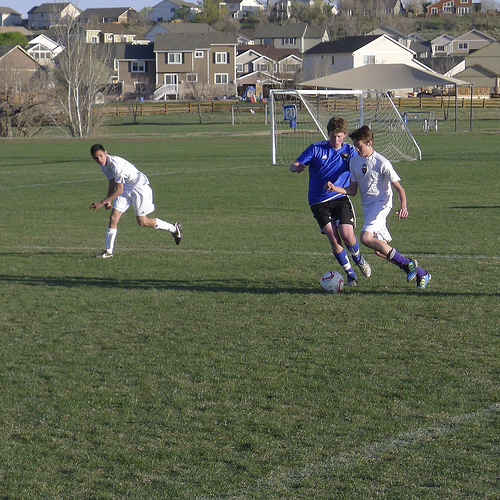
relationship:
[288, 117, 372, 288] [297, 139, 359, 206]
boy wearing uniform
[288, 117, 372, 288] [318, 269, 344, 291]
boy kicking ball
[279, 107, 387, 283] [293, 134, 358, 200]
boy wearing t-shirt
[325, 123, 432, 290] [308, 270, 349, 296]
player run for ball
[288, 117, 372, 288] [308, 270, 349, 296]
boy run for ball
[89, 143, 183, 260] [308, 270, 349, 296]
children run for ball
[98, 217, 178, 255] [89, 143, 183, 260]
white socks on children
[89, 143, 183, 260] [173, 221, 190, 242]
children wearing cleats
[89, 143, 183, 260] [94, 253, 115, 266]
children wearing cleats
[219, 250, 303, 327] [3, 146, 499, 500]
shadows on field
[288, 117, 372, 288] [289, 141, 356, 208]
boy wearing a blue jersey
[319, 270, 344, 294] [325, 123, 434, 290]
ball chased by player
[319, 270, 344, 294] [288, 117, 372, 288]
ball chased by boy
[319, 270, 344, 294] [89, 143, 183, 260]
ball chased by children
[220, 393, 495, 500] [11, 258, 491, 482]
line on field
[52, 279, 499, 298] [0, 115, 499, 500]
shadows on field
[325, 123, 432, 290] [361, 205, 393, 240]
player wearing shorts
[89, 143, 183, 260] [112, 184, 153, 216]
children wearing shorts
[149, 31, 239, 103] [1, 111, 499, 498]
house behind soccer field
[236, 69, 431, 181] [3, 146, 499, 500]
goal on field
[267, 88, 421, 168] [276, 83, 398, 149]
goal a mesh cage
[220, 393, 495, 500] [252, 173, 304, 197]
line on field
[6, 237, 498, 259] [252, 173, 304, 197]
line on field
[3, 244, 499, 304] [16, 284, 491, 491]
shadows on grass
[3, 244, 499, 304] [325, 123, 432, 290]
shadows of player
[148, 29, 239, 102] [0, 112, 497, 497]
home skirts field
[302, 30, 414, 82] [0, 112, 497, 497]
home skirts field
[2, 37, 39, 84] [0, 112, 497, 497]
home skirts field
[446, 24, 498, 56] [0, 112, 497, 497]
home skirts field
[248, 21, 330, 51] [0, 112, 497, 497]
home skirts field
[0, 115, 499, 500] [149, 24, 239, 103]
field behind house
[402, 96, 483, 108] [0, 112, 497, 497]
fence around field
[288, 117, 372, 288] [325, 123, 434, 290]
boy opposes player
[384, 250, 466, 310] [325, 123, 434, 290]
shoes on player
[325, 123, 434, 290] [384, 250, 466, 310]
player wears shoes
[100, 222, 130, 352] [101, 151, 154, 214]
left shoe of player on left wearing white uniform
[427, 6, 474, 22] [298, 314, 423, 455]
house in upper right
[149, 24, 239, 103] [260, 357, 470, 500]
house with  visible windows in upper center